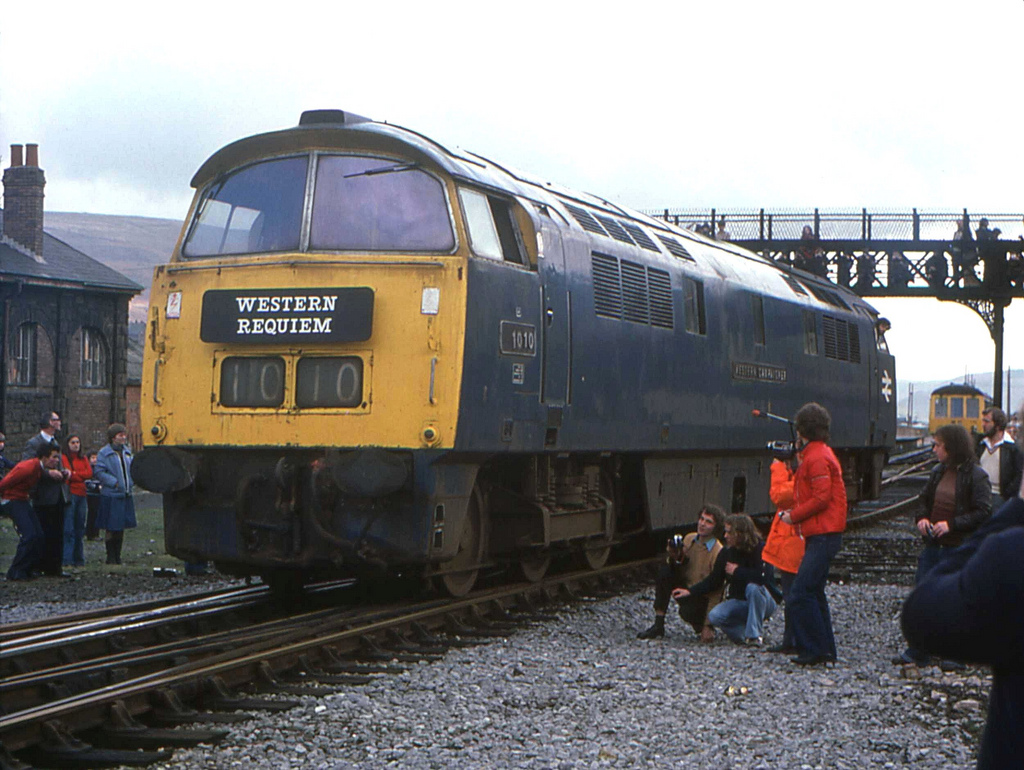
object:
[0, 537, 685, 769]
track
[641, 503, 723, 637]
person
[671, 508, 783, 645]
person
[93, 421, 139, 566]
person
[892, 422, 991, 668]
lady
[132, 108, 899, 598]
train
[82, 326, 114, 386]
window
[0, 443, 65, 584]
man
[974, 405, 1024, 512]
man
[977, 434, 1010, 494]
shirt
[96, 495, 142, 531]
skirt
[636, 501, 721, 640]
man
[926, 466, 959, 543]
shirt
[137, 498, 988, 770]
gravel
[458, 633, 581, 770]
grey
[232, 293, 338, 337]
logo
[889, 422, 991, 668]
woman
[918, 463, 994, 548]
jacket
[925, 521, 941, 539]
camera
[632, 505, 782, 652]
two people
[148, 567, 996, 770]
ground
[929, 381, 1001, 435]
train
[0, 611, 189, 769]
brown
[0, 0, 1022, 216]
sky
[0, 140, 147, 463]
building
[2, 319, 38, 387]
windows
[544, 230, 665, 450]
engine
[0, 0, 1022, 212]
sky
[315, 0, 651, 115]
clouds